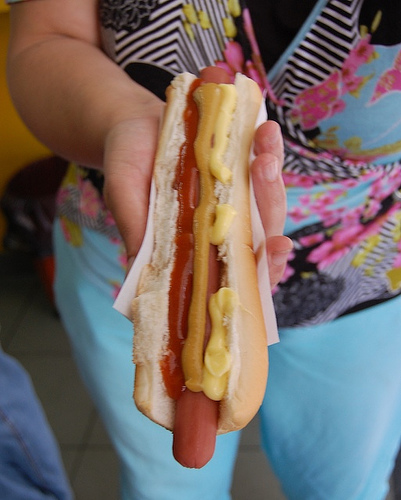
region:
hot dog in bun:
[173, 64, 237, 466]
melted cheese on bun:
[202, 84, 232, 395]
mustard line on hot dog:
[183, 82, 217, 394]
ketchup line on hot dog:
[166, 76, 197, 392]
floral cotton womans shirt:
[58, 0, 399, 329]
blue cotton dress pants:
[51, 218, 399, 498]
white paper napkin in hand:
[116, 86, 281, 345]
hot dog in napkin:
[133, 59, 270, 467]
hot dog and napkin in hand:
[115, 62, 279, 468]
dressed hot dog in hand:
[116, 63, 279, 469]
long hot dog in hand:
[123, 62, 291, 498]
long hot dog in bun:
[119, 66, 294, 469]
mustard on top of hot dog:
[191, 85, 227, 161]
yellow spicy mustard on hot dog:
[195, 79, 220, 120]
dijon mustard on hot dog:
[213, 110, 227, 146]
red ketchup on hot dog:
[156, 165, 194, 234]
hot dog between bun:
[147, 69, 236, 404]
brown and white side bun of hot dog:
[224, 314, 254, 368]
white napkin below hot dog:
[108, 236, 162, 293]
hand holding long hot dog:
[85, 67, 308, 245]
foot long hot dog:
[136, 43, 270, 469]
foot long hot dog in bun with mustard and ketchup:
[138, 60, 269, 466]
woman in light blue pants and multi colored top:
[8, 1, 398, 498]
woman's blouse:
[53, 0, 399, 331]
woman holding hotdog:
[10, 1, 399, 498]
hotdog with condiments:
[126, 60, 270, 465]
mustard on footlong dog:
[183, 82, 234, 399]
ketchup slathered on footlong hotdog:
[159, 78, 199, 400]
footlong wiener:
[173, 63, 216, 469]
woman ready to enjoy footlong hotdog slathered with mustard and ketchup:
[2, 0, 399, 497]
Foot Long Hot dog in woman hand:
[131, 65, 267, 470]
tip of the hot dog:
[170, 419, 219, 468]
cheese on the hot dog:
[205, 291, 228, 396]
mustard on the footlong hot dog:
[182, 85, 208, 394]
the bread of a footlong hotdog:
[233, 266, 269, 430]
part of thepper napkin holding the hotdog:
[111, 293, 133, 321]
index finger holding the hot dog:
[268, 236, 290, 284]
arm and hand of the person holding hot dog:
[4, 44, 146, 257]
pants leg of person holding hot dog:
[268, 297, 400, 495]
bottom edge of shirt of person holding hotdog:
[55, 172, 95, 230]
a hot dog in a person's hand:
[131, 56, 297, 467]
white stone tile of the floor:
[60, 417, 100, 472]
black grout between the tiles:
[71, 430, 91, 461]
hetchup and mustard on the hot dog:
[165, 133, 247, 405]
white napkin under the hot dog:
[247, 233, 287, 340]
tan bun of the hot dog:
[236, 213, 262, 356]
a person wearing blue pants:
[51, 212, 399, 499]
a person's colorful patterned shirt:
[63, 1, 392, 315]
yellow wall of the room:
[0, 118, 36, 161]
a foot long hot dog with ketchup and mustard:
[136, 56, 275, 465]